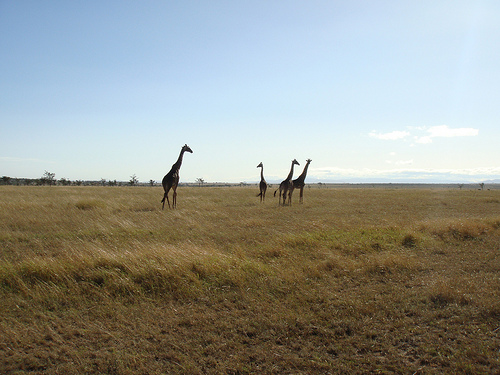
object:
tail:
[272, 183, 281, 196]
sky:
[2, 2, 497, 182]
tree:
[198, 178, 206, 188]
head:
[182, 142, 194, 153]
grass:
[0, 184, 500, 375]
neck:
[170, 151, 188, 167]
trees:
[128, 176, 140, 188]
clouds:
[364, 130, 416, 148]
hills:
[333, 169, 498, 185]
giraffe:
[290, 157, 314, 206]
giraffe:
[157, 142, 195, 209]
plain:
[0, 184, 500, 375]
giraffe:
[255, 160, 271, 201]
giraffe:
[269, 159, 303, 207]